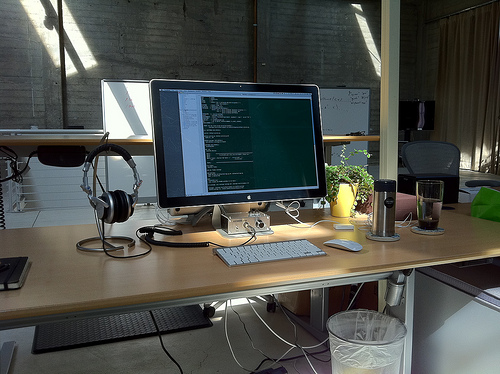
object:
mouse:
[322, 238, 363, 253]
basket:
[325, 307, 409, 374]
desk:
[1, 207, 500, 374]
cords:
[223, 300, 299, 373]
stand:
[98, 132, 112, 195]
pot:
[329, 178, 360, 218]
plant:
[320, 147, 375, 206]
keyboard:
[212, 238, 328, 268]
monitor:
[148, 77, 329, 210]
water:
[416, 198, 443, 230]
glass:
[415, 179, 445, 231]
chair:
[400, 140, 472, 205]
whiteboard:
[100, 79, 154, 140]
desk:
[1, 135, 384, 165]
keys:
[234, 259, 244, 265]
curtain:
[430, 0, 500, 176]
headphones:
[79, 143, 143, 225]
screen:
[157, 88, 320, 198]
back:
[401, 139, 462, 174]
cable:
[146, 307, 185, 374]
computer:
[146, 76, 329, 236]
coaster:
[364, 232, 401, 243]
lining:
[325, 307, 410, 370]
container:
[370, 178, 397, 237]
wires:
[101, 220, 256, 259]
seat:
[458, 189, 473, 205]